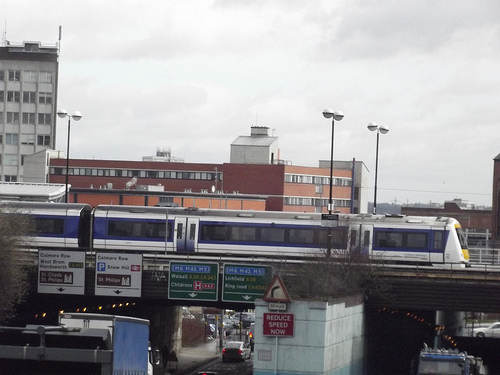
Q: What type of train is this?
A: Passenger train.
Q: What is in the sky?
A: Clouds.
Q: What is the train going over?
A: Bridge.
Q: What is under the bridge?
A: Highway.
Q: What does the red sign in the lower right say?
A: Reduce Speed Now.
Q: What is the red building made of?
A: Brick.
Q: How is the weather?
A: Clear.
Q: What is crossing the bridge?
A: A train.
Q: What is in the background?
A: Brick building.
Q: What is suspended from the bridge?
A: Road signs.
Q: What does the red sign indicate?
A: Reduce speed.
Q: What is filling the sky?
A: Clouds.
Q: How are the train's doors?
A: Closed.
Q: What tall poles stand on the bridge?
A: Light poles.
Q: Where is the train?
A: The bridge.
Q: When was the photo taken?
A: Daytime.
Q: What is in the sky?
A: Clouds.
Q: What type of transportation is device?
A: Train.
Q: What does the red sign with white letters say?
A: Reduce Speed Ahead.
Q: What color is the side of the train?
A: White and blue.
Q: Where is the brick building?
A: Background.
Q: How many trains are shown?
A: One.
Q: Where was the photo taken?
A: From an elevated train.